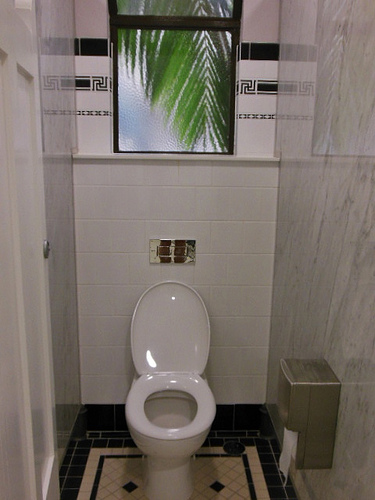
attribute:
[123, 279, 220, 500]
toilet — white, clean, oval shaped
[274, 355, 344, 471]
toilet paper holder — chrome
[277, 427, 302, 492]
toilet paper — white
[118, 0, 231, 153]
palm tree — green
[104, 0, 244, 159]
through window — trimmed in black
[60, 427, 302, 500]
floor — black, beige, tiled, white, bathroom floor, white tile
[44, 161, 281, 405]
walls — tiled in white, white, tile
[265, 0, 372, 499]
wall — grey, white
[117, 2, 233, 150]
window glass — frosted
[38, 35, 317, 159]
wall — black, tiled, white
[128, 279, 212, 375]
toilet seat — raised, white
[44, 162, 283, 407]
tile wall — white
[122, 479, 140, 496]
tile — black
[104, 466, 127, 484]
floor tile — white, beige